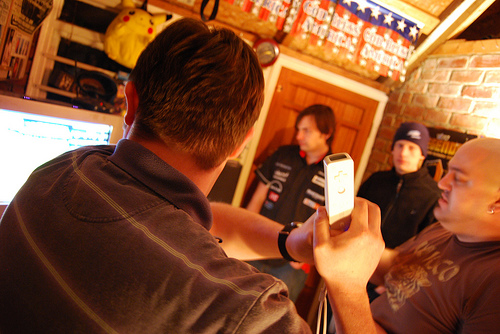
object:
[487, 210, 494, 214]
earring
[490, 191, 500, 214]
ear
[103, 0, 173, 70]
pikachu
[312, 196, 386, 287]
hand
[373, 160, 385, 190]
ground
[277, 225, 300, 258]
wristwatch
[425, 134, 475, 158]
poster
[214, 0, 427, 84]
banner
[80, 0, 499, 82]
wall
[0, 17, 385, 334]
man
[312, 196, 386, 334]
man's hand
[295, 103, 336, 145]
hair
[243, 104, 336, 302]
man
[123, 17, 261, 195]
head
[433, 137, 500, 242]
man's head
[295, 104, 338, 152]
man's head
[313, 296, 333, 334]
cord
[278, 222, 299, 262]
watch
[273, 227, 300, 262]
wrist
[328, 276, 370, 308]
wrist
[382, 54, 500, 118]
bricks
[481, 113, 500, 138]
light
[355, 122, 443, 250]
man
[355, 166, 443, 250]
jacket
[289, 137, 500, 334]
man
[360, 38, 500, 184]
wall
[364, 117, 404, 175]
bricks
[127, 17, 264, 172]
brown hair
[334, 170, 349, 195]
button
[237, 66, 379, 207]
door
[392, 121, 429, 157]
beanie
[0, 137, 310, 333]
shirt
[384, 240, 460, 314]
design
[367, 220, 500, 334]
shirt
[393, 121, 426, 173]
head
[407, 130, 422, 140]
design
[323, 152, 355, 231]
game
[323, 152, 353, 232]
remote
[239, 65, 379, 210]
closed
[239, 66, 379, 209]
wood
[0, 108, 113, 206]
powered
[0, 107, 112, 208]
screen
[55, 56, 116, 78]
wall